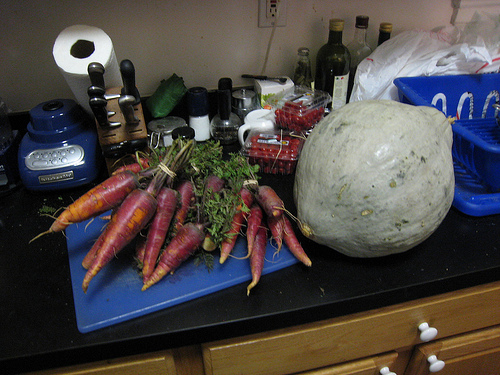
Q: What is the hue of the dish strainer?
A: Blue.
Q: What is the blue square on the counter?
A: A cutting board.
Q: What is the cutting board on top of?
A: A black counter.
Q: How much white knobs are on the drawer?
A: One.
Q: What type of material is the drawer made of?
A: Wood.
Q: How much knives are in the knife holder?
A: Four.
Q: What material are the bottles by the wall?
A: Glass.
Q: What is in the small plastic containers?
A: Grape tomatoes.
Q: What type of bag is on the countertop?
A: A white plastic bag.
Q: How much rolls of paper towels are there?
A: One.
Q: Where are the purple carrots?
A: On the blue cutting board.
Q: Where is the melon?
A: To the right of the carrots.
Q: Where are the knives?
A: In the knife rack, behind the carrots.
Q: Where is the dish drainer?
A: On the right of the melon.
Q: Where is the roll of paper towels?
A: Behind the knife rack.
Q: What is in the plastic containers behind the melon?
A: Tomatoes.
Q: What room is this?
A: Kitchen.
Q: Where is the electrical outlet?
A: On the wall.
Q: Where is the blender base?
A: To the left of the knives.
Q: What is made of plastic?
A: Grocery bags.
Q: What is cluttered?
A: The countertop.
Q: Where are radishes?
A: On cutting board.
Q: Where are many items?
A: On countertop.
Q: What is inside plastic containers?
A: Cherry tomatoes.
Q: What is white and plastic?
A: Bags.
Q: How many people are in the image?
A: 0.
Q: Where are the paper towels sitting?
A: On top of the knives.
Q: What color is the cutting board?
A: Blue.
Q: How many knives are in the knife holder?
A: 5.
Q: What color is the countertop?
A: Black.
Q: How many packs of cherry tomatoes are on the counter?
A: 2.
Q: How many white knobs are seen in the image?
A: 3.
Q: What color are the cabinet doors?
A: Brown.